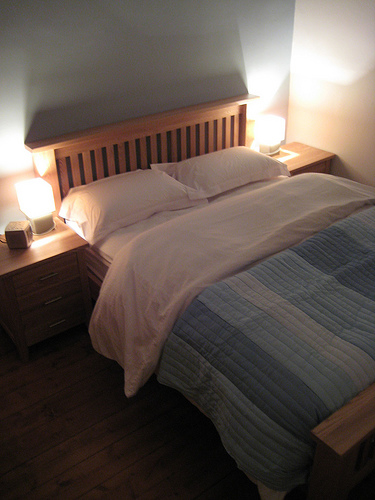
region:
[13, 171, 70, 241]
Light on nightstand.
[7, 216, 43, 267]
Alarm clock on the nightstand.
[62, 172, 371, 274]
Pillows on the bed.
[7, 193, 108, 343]
Nightstand with three drawers.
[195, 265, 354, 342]
Blue comforter on the bed.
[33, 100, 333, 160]
Wooden headboard.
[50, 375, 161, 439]
Hardwood floor with wide planks.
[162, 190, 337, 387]
Comforter on the bed.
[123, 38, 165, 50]
Blue wall in bedroom.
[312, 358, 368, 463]
Wooden foot board at the end of the bed.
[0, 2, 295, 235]
Wall behind bed is light blue.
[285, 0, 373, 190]
Wall on right of bed is white.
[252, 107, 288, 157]
There is a lamp on the nightstand.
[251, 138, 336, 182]
Nightstand made of light wood.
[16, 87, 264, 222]
Headboard matches the nightstands.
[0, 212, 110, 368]
Nightstand on left side has drawers.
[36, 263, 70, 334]
Three drawer handles for drawers.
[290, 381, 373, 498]
Footboard matches the headboard.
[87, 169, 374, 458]
The bedding is turned down.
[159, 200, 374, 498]
Comforter has various blue shade stripes.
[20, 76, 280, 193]
headboard of wooden slats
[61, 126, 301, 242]
two pillows side by side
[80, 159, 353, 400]
white comforter turned down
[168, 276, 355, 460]
quilted blue and white striped blanket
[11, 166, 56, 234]
cube of white light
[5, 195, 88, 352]
bedside table with three drawers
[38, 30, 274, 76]
blue wall behind bed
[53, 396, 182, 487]
wooden floor in bedroom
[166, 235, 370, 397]
fold line across blanket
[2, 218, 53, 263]
clock on top of table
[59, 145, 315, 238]
two white pillows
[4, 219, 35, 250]
a bedside alarm clock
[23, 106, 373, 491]
a bed that is properly made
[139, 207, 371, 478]
covers made of several shades of blue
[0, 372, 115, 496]
clean wooden floors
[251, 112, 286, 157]
a white bedside lamp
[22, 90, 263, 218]
a wooden bed frame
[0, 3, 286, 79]
a white wall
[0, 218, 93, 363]
a wooden dresser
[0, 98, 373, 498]
a neat bedroom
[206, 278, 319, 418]
the blanket is blue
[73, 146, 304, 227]
the pillows are white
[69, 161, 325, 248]
the pillows on the bed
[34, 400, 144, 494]
the floor is brown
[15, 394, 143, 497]
the floor is made of wood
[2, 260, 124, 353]
the drawer is closed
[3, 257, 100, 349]
the drawer is made of wood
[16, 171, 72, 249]
the lamp is turned on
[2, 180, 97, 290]
the lamp is on side table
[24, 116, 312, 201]
the headboard is made of wood